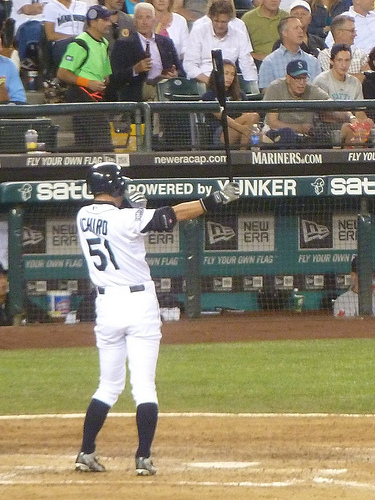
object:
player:
[75, 160, 240, 479]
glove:
[214, 182, 241, 205]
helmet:
[86, 161, 126, 199]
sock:
[134, 402, 158, 460]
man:
[262, 59, 358, 151]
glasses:
[289, 76, 309, 83]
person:
[334, 257, 375, 318]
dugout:
[0, 173, 375, 323]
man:
[111, 2, 191, 152]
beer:
[143, 41, 152, 75]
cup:
[330, 130, 343, 149]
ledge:
[0, 147, 375, 170]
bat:
[210, 48, 234, 183]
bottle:
[250, 124, 260, 152]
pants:
[90, 282, 162, 408]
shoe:
[75, 452, 108, 473]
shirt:
[75, 202, 155, 287]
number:
[86, 237, 120, 273]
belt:
[95, 281, 154, 295]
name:
[80, 217, 108, 235]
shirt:
[58, 30, 111, 88]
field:
[0, 317, 375, 500]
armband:
[76, 76, 90, 88]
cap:
[86, 5, 118, 23]